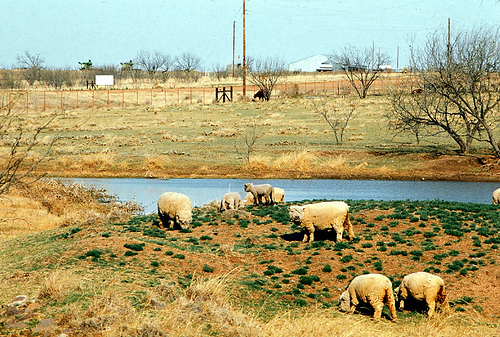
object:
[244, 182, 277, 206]
sheep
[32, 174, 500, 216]
river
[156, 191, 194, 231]
sheep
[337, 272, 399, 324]
sheep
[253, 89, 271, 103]
cow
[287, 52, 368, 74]
building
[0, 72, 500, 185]
field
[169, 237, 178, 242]
grass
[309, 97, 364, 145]
tree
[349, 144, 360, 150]
leaf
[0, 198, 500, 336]
dirt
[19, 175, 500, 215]
water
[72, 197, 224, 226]
ditch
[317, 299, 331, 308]
grass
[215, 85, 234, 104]
fence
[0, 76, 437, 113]
fence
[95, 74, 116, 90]
shed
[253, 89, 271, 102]
animal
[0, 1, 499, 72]
sky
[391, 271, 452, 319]
sheep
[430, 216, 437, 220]
plant